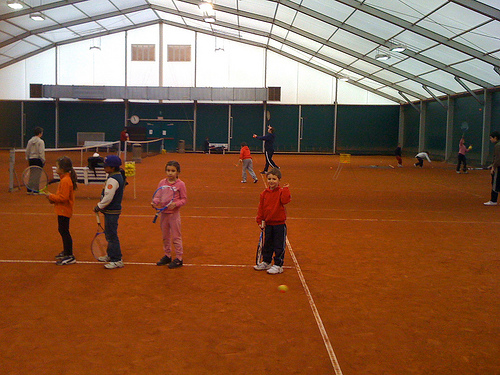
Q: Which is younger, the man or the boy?
A: The boy is younger than the man.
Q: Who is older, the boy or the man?
A: The man is older than the boy.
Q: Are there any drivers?
A: No, there are no drivers.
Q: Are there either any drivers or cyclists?
A: No, there are no drivers or cyclists.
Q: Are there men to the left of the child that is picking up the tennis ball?
A: Yes, there is a man to the left of the kid.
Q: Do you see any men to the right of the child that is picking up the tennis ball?
A: No, the man is to the left of the kid.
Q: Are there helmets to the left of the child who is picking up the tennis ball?
A: No, there is a man to the left of the kid.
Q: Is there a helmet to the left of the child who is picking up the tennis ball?
A: No, there is a man to the left of the kid.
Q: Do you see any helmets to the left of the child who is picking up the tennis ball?
A: No, there is a man to the left of the kid.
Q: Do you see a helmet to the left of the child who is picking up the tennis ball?
A: No, there is a man to the left of the kid.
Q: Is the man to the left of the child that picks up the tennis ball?
A: Yes, the man is to the left of the kid.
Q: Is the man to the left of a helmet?
A: No, the man is to the left of the kid.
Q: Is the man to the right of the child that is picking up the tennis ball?
A: No, the man is to the left of the child.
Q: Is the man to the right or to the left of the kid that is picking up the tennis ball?
A: The man is to the left of the child.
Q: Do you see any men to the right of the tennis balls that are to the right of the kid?
A: Yes, there is a man to the right of the tennis balls.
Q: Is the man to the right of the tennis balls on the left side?
A: Yes, the man is to the right of the tennis balls.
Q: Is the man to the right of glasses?
A: No, the man is to the right of the tennis balls.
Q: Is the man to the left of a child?
A: No, the man is to the right of a child.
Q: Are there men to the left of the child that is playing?
A: Yes, there is a man to the left of the child.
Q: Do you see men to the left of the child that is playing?
A: Yes, there is a man to the left of the child.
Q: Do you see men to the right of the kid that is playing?
A: No, the man is to the left of the kid.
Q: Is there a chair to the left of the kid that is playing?
A: No, there is a man to the left of the kid.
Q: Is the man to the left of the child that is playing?
A: Yes, the man is to the left of the kid.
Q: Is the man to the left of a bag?
A: No, the man is to the left of the kid.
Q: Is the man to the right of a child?
A: No, the man is to the left of a child.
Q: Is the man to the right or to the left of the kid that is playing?
A: The man is to the left of the kid.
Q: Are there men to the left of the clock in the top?
A: No, the man is to the right of the clock.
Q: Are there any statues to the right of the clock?
A: No, there is a man to the right of the clock.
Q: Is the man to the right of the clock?
A: Yes, the man is to the right of the clock.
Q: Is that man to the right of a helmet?
A: No, the man is to the right of the clock.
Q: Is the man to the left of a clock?
A: No, the man is to the right of a clock.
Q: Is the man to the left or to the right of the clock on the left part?
A: The man is to the right of the clock.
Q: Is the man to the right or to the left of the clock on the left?
A: The man is to the right of the clock.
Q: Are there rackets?
A: Yes, there is a racket.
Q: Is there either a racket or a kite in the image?
A: Yes, there is a racket.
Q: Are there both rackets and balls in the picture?
A: Yes, there are both a racket and balls.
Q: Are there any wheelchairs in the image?
A: No, there are no wheelchairs.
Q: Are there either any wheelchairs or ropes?
A: No, there are no wheelchairs or ropes.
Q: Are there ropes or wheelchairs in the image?
A: No, there are no wheelchairs or ropes.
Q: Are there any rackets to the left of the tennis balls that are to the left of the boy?
A: Yes, there is a racket to the left of the tennis balls.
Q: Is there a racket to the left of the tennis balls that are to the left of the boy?
A: Yes, there is a racket to the left of the tennis balls.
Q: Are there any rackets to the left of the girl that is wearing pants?
A: Yes, there is a racket to the left of the girl.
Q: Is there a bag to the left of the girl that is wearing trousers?
A: No, there is a racket to the left of the girl.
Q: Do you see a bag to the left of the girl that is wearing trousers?
A: No, there is a racket to the left of the girl.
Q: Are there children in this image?
A: Yes, there is a child.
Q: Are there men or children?
A: Yes, there is a child.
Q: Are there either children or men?
A: Yes, there is a child.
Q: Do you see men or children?
A: Yes, there is a child.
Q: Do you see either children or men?
A: Yes, there is a child.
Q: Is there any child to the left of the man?
A: Yes, there is a child to the left of the man.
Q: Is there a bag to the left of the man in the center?
A: No, there is a child to the left of the man.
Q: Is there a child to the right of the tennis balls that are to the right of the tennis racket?
A: Yes, there is a child to the right of the tennis balls.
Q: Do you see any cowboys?
A: No, there are no cowboys.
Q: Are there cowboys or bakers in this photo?
A: No, there are no cowboys or bakers.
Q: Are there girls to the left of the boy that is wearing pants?
A: Yes, there is a girl to the left of the boy.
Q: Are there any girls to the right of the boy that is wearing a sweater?
A: No, the girl is to the left of the boy.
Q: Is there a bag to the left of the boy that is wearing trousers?
A: No, there is a girl to the left of the boy.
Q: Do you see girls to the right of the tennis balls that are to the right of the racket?
A: Yes, there is a girl to the right of the tennis balls.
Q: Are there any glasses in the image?
A: No, there are no glasses.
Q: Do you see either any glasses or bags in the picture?
A: No, there are no glasses or bags.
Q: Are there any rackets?
A: Yes, there is a racket.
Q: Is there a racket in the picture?
A: Yes, there is a racket.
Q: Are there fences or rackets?
A: Yes, there is a racket.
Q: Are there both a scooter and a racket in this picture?
A: No, there is a racket but no scooters.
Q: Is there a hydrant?
A: No, there are no fire hydrants.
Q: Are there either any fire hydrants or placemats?
A: No, there are no fire hydrants or placemats.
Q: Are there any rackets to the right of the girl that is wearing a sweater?
A: Yes, there is a racket to the right of the girl.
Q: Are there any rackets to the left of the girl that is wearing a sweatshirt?
A: No, the racket is to the right of the girl.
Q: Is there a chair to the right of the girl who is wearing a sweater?
A: No, there is a racket to the right of the girl.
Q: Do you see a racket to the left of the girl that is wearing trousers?
A: Yes, there is a racket to the left of the girl.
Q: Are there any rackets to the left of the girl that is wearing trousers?
A: Yes, there is a racket to the left of the girl.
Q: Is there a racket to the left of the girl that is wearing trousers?
A: Yes, there is a racket to the left of the girl.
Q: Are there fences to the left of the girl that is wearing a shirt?
A: No, there is a racket to the left of the girl.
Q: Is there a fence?
A: No, there are no fences.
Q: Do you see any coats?
A: Yes, there is a coat.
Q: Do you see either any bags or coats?
A: Yes, there is a coat.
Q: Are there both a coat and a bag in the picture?
A: No, there is a coat but no bags.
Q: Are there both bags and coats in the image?
A: No, there is a coat but no bags.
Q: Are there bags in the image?
A: No, there are no bags.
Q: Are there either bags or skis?
A: No, there are no bags or skis.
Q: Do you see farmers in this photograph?
A: No, there are no farmers.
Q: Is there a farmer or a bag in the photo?
A: No, there are no farmers or bags.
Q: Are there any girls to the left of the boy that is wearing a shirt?
A: Yes, there is a girl to the left of the boy.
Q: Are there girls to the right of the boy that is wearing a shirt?
A: No, the girl is to the left of the boy.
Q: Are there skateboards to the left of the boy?
A: No, there is a girl to the left of the boy.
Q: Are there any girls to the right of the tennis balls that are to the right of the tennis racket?
A: Yes, there is a girl to the right of the tennis balls.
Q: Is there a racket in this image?
A: Yes, there is a racket.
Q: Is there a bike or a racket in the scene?
A: Yes, there is a racket.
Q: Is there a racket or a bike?
A: Yes, there is a racket.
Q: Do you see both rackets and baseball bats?
A: No, there is a racket but no baseball bats.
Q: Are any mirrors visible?
A: No, there are no mirrors.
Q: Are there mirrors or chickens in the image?
A: No, there are no mirrors or chickens.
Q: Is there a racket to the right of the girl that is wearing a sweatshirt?
A: Yes, there is a racket to the right of the girl.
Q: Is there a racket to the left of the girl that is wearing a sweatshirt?
A: No, the racket is to the right of the girl.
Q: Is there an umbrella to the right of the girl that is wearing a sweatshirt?
A: No, there is a racket to the right of the girl.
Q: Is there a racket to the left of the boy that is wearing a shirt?
A: Yes, there is a racket to the left of the boy.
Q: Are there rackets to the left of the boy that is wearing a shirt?
A: Yes, there is a racket to the left of the boy.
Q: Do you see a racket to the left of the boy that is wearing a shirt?
A: Yes, there is a racket to the left of the boy.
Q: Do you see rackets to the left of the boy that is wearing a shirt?
A: Yes, there is a racket to the left of the boy.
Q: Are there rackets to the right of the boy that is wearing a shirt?
A: No, the racket is to the left of the boy.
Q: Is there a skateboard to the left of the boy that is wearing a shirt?
A: No, there is a racket to the left of the boy.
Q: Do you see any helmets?
A: No, there are no helmets.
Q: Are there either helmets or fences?
A: No, there are no helmets or fences.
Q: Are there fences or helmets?
A: No, there are no helmets or fences.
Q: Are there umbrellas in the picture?
A: No, there are no umbrellas.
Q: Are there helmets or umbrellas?
A: No, there are no umbrellas or helmets.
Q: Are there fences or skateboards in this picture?
A: No, there are no fences or skateboards.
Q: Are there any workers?
A: No, there are no workers.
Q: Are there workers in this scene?
A: No, there are no workers.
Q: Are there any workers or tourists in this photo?
A: No, there are no workers or tourists.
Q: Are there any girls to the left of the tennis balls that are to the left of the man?
A: Yes, there is a girl to the left of the tennis balls.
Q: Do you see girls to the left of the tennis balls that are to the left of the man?
A: Yes, there is a girl to the left of the tennis balls.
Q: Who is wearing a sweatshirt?
A: The girl is wearing a sweatshirt.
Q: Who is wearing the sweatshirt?
A: The girl is wearing a sweatshirt.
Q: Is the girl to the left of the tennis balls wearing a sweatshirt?
A: Yes, the girl is wearing a sweatshirt.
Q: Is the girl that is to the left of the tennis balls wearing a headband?
A: No, the girl is wearing a sweatshirt.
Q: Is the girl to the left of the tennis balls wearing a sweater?
A: Yes, the girl is wearing a sweater.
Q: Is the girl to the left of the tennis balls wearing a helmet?
A: No, the girl is wearing a sweater.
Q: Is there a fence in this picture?
A: No, there are no fences.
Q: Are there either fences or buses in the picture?
A: No, there are no fences or buses.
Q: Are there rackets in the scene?
A: Yes, there is a racket.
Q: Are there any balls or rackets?
A: Yes, there is a racket.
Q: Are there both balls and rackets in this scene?
A: Yes, there are both a racket and a ball.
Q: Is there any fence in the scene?
A: No, there are no fences.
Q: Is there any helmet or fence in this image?
A: No, there are no fences or helmets.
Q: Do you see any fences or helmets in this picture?
A: No, there are no fences or helmets.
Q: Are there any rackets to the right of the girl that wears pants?
A: Yes, there is a racket to the right of the girl.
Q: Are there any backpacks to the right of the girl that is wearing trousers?
A: No, there is a racket to the right of the girl.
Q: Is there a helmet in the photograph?
A: No, there are no helmets.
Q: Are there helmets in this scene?
A: No, there are no helmets.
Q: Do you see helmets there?
A: No, there are no helmets.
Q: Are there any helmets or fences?
A: No, there are no helmets or fences.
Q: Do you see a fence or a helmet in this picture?
A: No, there are no helmets or fences.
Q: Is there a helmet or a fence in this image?
A: No, there are no helmets or fences.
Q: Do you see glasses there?
A: No, there are no glasses.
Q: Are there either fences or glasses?
A: No, there are no glasses or fences.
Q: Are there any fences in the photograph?
A: No, there are no fences.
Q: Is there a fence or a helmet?
A: No, there are no fences or helmets.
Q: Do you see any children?
A: Yes, there is a child.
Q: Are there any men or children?
A: Yes, there is a child.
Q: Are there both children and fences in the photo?
A: No, there is a child but no fences.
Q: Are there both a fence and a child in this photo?
A: No, there is a child but no fences.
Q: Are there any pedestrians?
A: No, there are no pedestrians.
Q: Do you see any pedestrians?
A: No, there are no pedestrians.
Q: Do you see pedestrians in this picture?
A: No, there are no pedestrians.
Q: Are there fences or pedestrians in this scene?
A: No, there are no pedestrians or fences.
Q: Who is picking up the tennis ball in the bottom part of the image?
A: The child is picking up the tennis ball.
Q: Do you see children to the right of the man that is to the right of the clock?
A: Yes, there is a child to the right of the man.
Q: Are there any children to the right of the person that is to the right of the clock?
A: Yes, there is a child to the right of the man.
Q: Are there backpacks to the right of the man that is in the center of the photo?
A: No, there is a child to the right of the man.